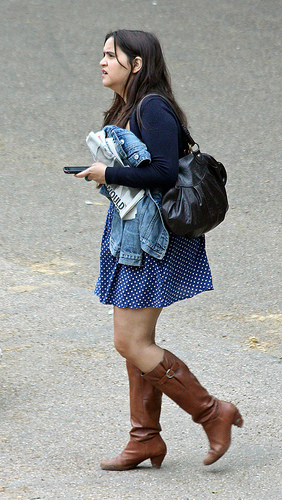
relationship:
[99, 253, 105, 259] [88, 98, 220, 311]
dot on dress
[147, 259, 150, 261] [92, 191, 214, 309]
dot adorning dress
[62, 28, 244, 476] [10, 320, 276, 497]
person walking on sidewalk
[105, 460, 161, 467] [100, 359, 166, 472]
bottom of shoe